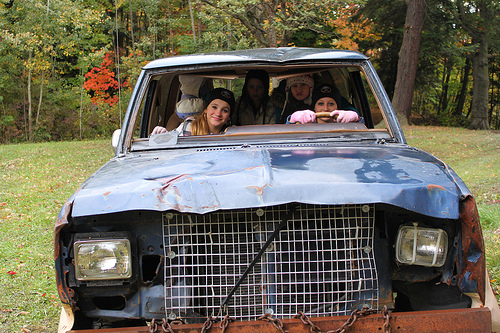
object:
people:
[196, 83, 354, 125]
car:
[67, 52, 496, 321]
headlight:
[396, 221, 464, 283]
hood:
[103, 147, 445, 223]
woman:
[180, 92, 243, 137]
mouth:
[208, 115, 229, 122]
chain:
[159, 304, 392, 332]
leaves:
[88, 67, 114, 97]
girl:
[288, 90, 363, 125]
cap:
[315, 82, 333, 95]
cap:
[287, 74, 320, 87]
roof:
[168, 49, 358, 65]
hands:
[294, 112, 363, 120]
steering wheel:
[283, 108, 375, 128]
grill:
[171, 202, 369, 300]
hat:
[201, 90, 236, 103]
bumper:
[150, 309, 497, 332]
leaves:
[40, 20, 91, 48]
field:
[13, 139, 130, 318]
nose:
[216, 110, 224, 118]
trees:
[19, 15, 499, 103]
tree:
[85, 48, 129, 141]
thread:
[242, 226, 279, 288]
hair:
[192, 109, 207, 135]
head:
[207, 92, 231, 130]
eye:
[212, 104, 229, 111]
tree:
[374, 3, 466, 130]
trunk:
[397, 34, 424, 106]